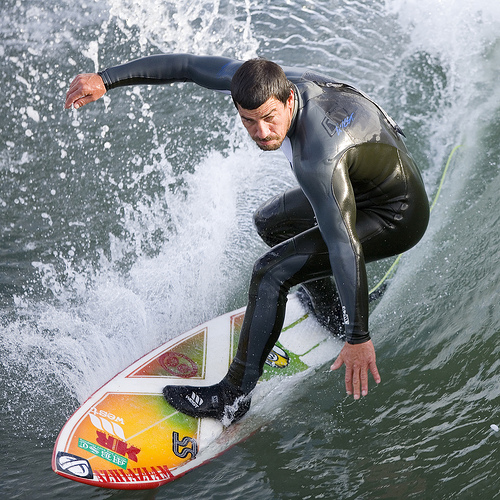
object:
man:
[62, 51, 430, 426]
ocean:
[0, 0, 498, 499]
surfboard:
[50, 291, 348, 492]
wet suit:
[96, 52, 429, 394]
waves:
[407, 8, 500, 374]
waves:
[1, 141, 239, 343]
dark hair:
[229, 57, 298, 112]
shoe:
[160, 379, 253, 426]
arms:
[291, 167, 369, 345]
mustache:
[249, 134, 280, 143]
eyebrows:
[257, 106, 278, 118]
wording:
[92, 463, 175, 483]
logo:
[54, 450, 94, 482]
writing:
[171, 430, 199, 463]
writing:
[319, 103, 357, 138]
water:
[284, 395, 499, 500]